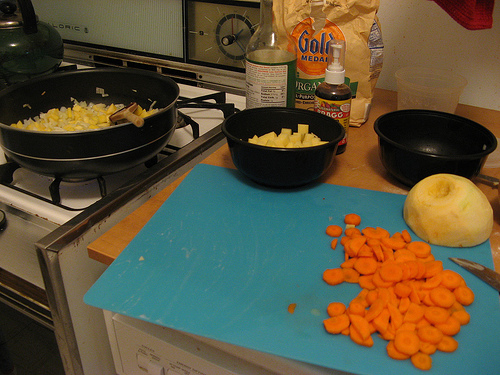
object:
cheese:
[251, 123, 329, 148]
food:
[318, 211, 474, 372]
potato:
[402, 173, 494, 248]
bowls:
[221, 106, 499, 191]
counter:
[86, 88, 500, 273]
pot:
[0, 68, 180, 159]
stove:
[0, 150, 180, 211]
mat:
[81, 163, 500, 375]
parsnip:
[401, 172, 495, 248]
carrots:
[325, 212, 475, 369]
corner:
[85, 234, 105, 263]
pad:
[79, 163, 500, 375]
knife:
[446, 256, 500, 294]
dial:
[213, 13, 256, 62]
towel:
[429, 0, 496, 32]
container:
[244, 0, 297, 111]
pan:
[0, 123, 177, 179]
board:
[83, 162, 500, 373]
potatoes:
[248, 124, 329, 148]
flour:
[269, 0, 386, 129]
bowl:
[371, 108, 498, 191]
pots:
[0, 68, 498, 190]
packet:
[269, 0, 385, 129]